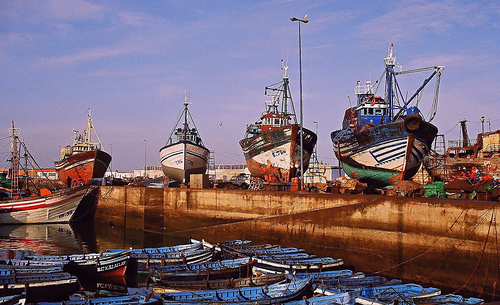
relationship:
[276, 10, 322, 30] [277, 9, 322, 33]
bird on top of street light